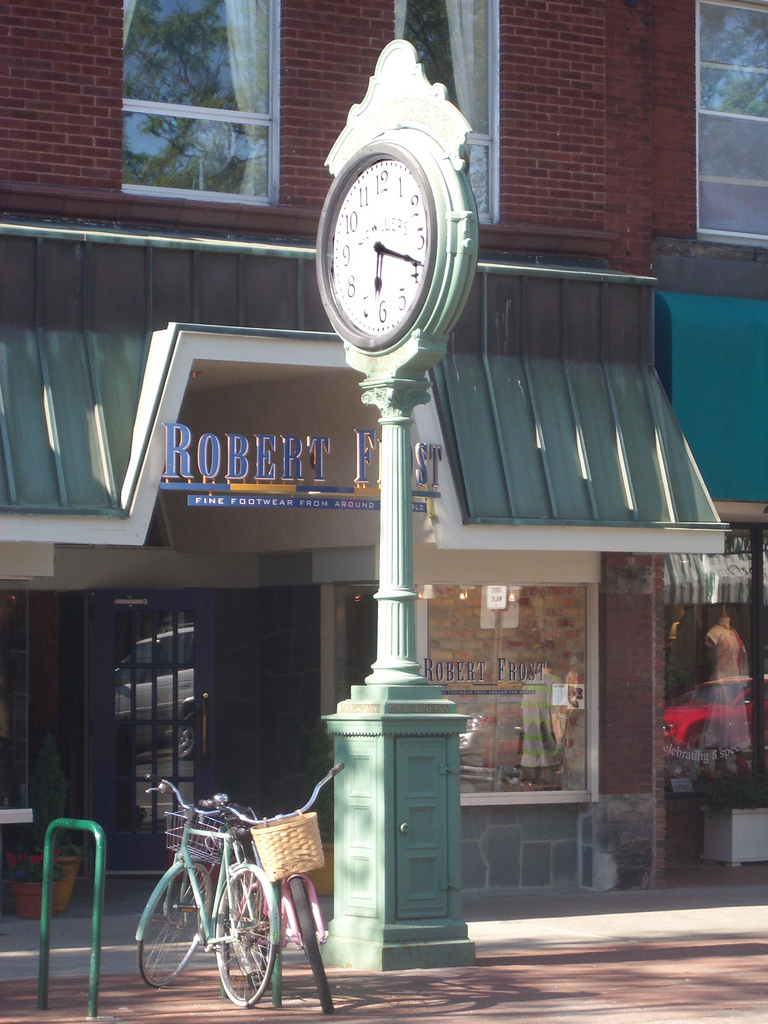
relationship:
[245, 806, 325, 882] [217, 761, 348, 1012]
basket on bike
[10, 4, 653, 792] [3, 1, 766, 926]
wall on side of building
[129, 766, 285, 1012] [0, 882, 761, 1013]
bikes on sidewalk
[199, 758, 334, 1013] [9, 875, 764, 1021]
bicycle on sidewalk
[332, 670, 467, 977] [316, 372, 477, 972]
base of pole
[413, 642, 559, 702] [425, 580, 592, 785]
lettering on store window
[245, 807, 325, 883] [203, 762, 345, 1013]
basket on bicycle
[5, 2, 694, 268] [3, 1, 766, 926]
wall of building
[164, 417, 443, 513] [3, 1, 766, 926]
sign on building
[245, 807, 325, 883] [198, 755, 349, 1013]
basket attached to bicycle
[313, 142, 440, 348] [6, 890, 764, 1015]
clock in street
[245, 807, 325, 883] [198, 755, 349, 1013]
basket on front bicycle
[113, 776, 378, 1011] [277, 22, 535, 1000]
bikes leaning against pole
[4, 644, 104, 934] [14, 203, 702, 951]
plants outside shop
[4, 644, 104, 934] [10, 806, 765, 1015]
plants on ground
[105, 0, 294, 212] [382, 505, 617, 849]
curtains in window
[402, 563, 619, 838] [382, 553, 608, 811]
window has reflections